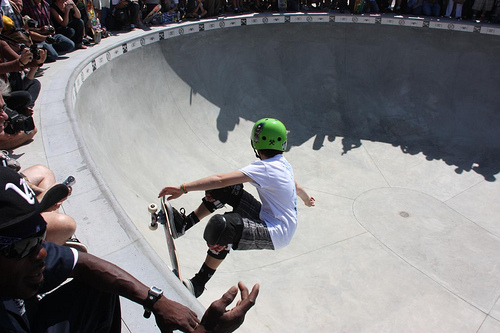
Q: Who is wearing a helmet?
A: Skateboarder.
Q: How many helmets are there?
A: One.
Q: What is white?
A: Skateboarder's shirt.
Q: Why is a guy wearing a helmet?
A: Guy is skateboarding.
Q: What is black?
A: Man's hat.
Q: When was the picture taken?
A: Daytime.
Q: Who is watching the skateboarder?
A: Spectators.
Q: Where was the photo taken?
A: At a skatepark.